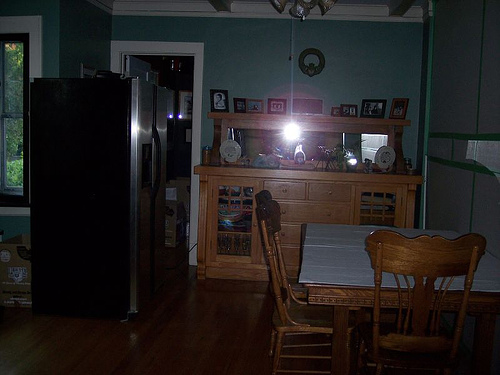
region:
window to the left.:
[0, 12, 47, 214]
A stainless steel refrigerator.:
[21, 68, 176, 325]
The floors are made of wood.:
[176, 304, 251, 371]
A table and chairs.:
[244, 185, 499, 371]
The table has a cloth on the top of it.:
[282, 212, 499, 312]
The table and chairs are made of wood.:
[241, 186, 498, 373]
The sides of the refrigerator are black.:
[22, 70, 175, 329]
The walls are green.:
[353, 41, 401, 78]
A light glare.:
[274, 117, 311, 147]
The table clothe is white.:
[289, 213, 496, 300]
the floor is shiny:
[155, 272, 273, 371]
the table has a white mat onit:
[300, 221, 498, 303]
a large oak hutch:
[187, 112, 418, 294]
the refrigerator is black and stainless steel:
[30, 77, 180, 332]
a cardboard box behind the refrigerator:
[2, 229, 35, 312]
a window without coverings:
[3, 32, 26, 210]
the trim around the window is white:
[2, 12, 50, 57]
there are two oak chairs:
[241, 190, 481, 372]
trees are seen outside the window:
[4, 48, 20, 190]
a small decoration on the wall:
[292, 44, 332, 82]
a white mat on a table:
[297, 213, 499, 292]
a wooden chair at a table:
[366, 222, 477, 370]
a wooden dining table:
[297, 216, 488, 367]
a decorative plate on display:
[218, 138, 246, 164]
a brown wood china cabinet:
[189, 99, 430, 301]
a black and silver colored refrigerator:
[32, 61, 174, 326]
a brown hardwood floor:
[2, 276, 496, 373]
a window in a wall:
[1, 10, 43, 219]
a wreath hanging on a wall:
[290, 45, 332, 77]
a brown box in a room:
[2, 226, 45, 314]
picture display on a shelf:
[204, 81, 421, 129]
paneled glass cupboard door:
[196, 168, 266, 283]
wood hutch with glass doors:
[192, 88, 432, 280]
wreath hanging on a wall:
[295, 38, 334, 87]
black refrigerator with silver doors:
[24, 63, 181, 339]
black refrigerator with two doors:
[23, 63, 178, 340]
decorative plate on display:
[367, 141, 405, 175]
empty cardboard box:
[0, 223, 40, 315]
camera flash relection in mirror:
[266, 102, 325, 162]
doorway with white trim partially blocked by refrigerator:
[26, 21, 215, 336]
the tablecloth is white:
[253, 101, 378, 258]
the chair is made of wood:
[243, 175, 343, 340]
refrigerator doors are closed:
[114, 66, 176, 346]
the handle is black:
[153, 127, 173, 203]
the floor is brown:
[167, 287, 260, 372]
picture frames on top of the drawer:
[184, 75, 446, 126]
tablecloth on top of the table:
[288, 196, 479, 326]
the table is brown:
[308, 272, 392, 367]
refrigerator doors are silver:
[127, 76, 192, 343]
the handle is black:
[143, 117, 170, 237]